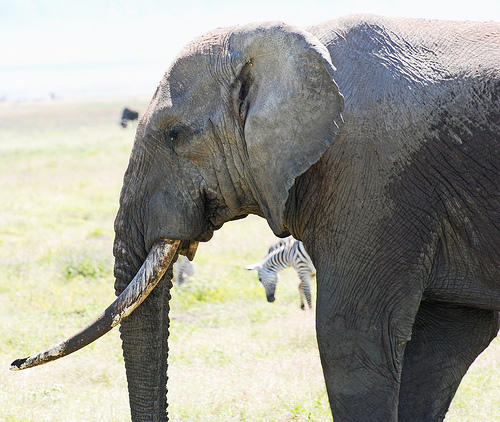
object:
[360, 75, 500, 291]
wet skin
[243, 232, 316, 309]
utility pole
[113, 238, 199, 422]
trunk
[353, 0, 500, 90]
sun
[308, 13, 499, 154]
back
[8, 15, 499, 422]
animal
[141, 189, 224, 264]
mouth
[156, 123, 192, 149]
eye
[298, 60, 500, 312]
wrinkles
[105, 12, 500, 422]
skin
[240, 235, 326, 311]
animal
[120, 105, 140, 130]
animal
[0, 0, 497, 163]
background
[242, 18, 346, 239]
ear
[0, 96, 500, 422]
grass